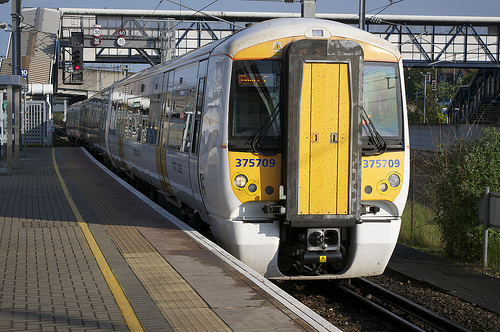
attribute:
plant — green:
[436, 125, 498, 262]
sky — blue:
[79, 0, 494, 10]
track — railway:
[54, 22, 435, 278]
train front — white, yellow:
[222, 17, 411, 280]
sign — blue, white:
[8, 63, 38, 85]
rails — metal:
[337, 275, 474, 329]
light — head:
[232, 170, 262, 194]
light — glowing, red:
[73, 62, 80, 72]